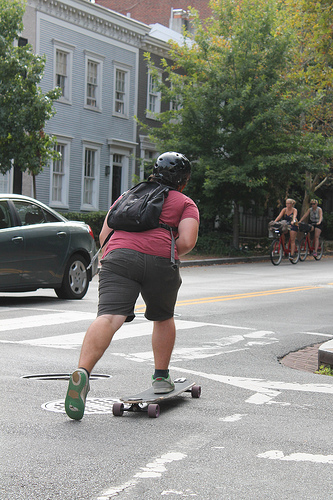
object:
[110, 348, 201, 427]
board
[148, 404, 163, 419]
wheels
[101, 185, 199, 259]
t-shirt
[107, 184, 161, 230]
backpack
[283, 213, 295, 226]
dress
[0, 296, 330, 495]
pavement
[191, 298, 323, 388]
crosswalk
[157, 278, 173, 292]
grey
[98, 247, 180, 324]
pants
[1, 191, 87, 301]
car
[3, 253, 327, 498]
street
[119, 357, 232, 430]
skateboard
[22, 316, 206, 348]
line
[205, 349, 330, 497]
ground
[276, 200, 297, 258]
woman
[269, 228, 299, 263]
bicycle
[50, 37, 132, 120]
windows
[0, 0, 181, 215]
building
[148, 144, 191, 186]
helmet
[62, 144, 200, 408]
skateboarder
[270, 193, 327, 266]
cyclist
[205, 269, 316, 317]
street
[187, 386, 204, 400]
wheel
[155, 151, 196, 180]
head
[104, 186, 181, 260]
back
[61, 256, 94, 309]
wheel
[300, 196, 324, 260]
cyclist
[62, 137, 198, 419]
person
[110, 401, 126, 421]
wheel